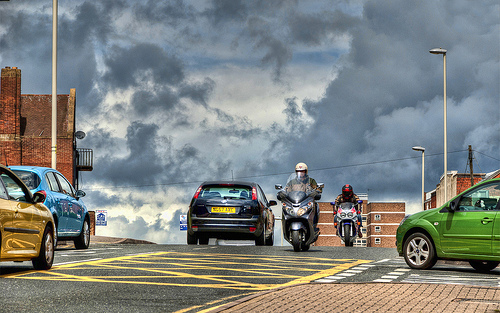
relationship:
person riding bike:
[284, 161, 324, 196] [272, 182, 324, 251]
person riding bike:
[330, 179, 364, 238] [328, 200, 364, 247]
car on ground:
[185, 181, 277, 247] [0, 238, 500, 313]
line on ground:
[114, 244, 314, 301] [0, 238, 500, 313]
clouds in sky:
[0, 0, 499, 245] [0, 0, 500, 242]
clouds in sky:
[0, 0, 499, 245] [5, 3, 493, 169]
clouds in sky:
[0, 0, 499, 245] [8, 11, 484, 218]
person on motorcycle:
[330, 179, 366, 235] [337, 201, 362, 249]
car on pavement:
[182, 174, 281, 252] [17, 231, 350, 309]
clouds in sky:
[0, 0, 499, 245] [220, 31, 345, 103]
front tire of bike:
[284, 224, 306, 251] [273, 159, 328, 254]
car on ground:
[395, 179, 498, 271] [362, 269, 498, 285]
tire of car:
[397, 228, 437, 269] [394, 174, 499, 276]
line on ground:
[6, 249, 372, 294] [48, 228, 371, 311]